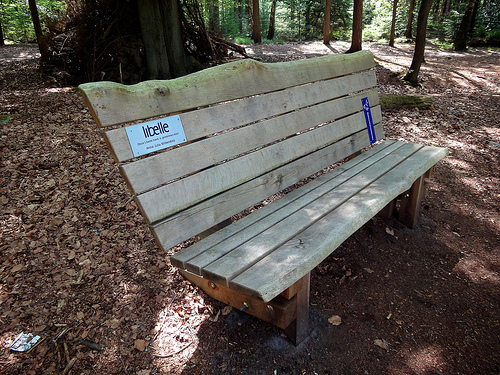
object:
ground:
[378, 252, 486, 372]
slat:
[78, 49, 406, 253]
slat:
[150, 138, 448, 259]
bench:
[76, 50, 451, 346]